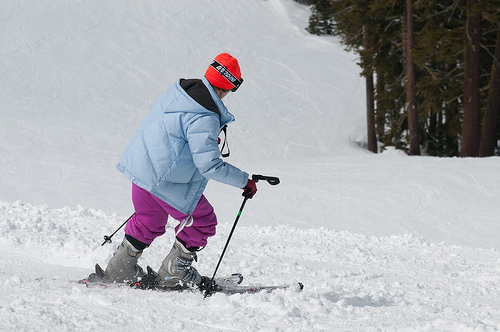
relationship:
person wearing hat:
[35, 52, 305, 294] [204, 50, 244, 90]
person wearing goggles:
[35, 52, 305, 294] [229, 73, 246, 94]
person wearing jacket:
[35, 52, 305, 294] [119, 74, 259, 217]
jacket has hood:
[119, 76, 247, 221] [157, 76, 216, 117]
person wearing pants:
[35, 52, 305, 294] [122, 179, 218, 253]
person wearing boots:
[35, 52, 305, 294] [104, 237, 209, 291]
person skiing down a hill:
[138, 45, 252, 277] [4, 206, 498, 330]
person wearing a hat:
[138, 45, 252, 277] [203, 54, 244, 92]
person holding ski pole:
[138, 45, 252, 277] [200, 174, 282, 299]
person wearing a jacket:
[138, 45, 252, 277] [119, 76, 247, 221]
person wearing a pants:
[138, 45, 252, 277] [122, 179, 218, 253]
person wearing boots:
[138, 45, 252, 277] [100, 234, 207, 288]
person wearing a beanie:
[138, 45, 252, 277] [203, 50, 242, 91]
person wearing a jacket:
[138, 45, 252, 277] [141, 105, 252, 183]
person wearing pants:
[138, 45, 252, 277] [96, 196, 220, 275]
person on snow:
[138, 45, 252, 277] [339, 194, 376, 229]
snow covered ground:
[3, 5, 498, 331] [347, 236, 489, 314]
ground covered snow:
[318, 230, 390, 265] [3, 5, 498, 331]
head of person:
[203, 49, 246, 92] [128, 41, 293, 231]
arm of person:
[182, 121, 261, 185] [143, 46, 361, 262]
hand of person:
[239, 178, 260, 201] [118, 40, 291, 328]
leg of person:
[113, 189, 156, 286] [75, 62, 300, 288]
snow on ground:
[3, 5, 498, 331] [375, 200, 447, 308]